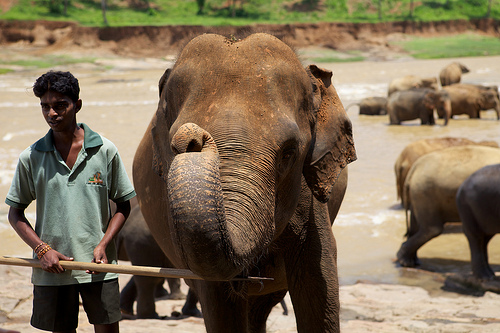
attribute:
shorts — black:
[31, 270, 133, 332]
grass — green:
[408, 31, 487, 61]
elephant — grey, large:
[118, 35, 354, 332]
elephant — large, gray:
[388, 87, 452, 129]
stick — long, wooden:
[0, 255, 275, 283]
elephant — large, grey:
[386, 70, 439, 96]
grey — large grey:
[477, 180, 497, 204]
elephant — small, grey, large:
[133, 29, 359, 331]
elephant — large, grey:
[387, 140, 498, 275]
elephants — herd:
[352, 59, 498, 125]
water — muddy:
[7, 58, 497, 290]